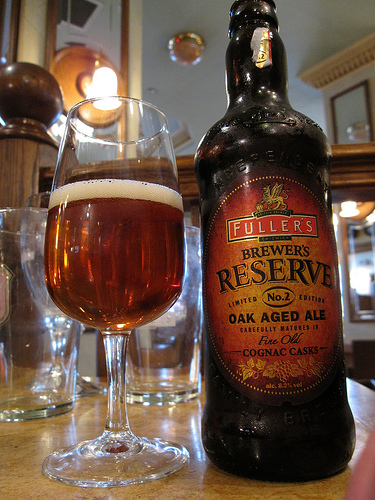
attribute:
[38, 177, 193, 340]
beer — oak age ale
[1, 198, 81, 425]
glass — empty, clear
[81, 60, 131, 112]
light — bright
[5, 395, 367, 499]
table — wood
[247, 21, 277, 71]
label — torn, half peeled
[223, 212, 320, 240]
fuller — company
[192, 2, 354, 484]
bottle — brewer's reserve ale, brown, beer